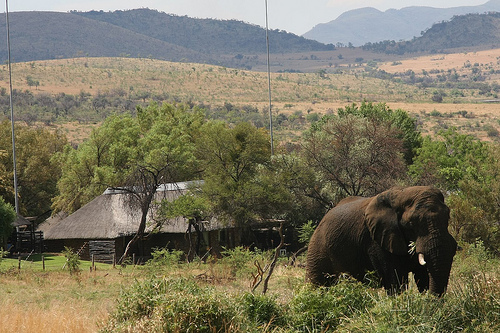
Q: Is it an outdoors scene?
A: Yes, it is outdoors.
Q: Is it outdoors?
A: Yes, it is outdoors.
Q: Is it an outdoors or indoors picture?
A: It is outdoors.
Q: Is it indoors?
A: No, it is outdoors.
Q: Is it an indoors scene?
A: No, it is outdoors.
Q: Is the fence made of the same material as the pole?
A: No, the fence is made of wood and the pole is made of metal.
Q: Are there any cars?
A: No, there are no cars.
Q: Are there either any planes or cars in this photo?
A: No, there are no cars or planes.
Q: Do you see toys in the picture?
A: No, there are no toys.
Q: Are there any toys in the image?
A: No, there are no toys.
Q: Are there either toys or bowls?
A: No, there are no toys or bowls.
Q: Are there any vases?
A: No, there are no vases.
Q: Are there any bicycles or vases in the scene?
A: No, there are no vases or bicycles.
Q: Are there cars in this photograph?
A: No, there are no cars.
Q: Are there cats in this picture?
A: No, there are no cats.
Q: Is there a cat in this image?
A: No, there are no cats.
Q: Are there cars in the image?
A: No, there are no cars.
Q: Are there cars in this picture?
A: No, there are no cars.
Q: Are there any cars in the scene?
A: No, there are no cars.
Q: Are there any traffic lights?
A: No, there are no traffic lights.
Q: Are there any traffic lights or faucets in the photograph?
A: No, there are no traffic lights or faucets.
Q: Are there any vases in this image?
A: No, there are no vases.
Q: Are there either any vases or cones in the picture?
A: No, there are no vases or cones.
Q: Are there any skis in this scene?
A: No, there are no skis.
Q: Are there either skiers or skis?
A: No, there are no skis or skiers.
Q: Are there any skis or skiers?
A: No, there are no skis or skiers.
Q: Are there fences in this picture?
A: Yes, there is a fence.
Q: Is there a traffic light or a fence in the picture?
A: Yes, there is a fence.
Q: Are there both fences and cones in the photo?
A: No, there is a fence but no cones.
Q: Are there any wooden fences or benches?
A: Yes, there is a wood fence.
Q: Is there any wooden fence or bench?
A: Yes, there is a wood fence.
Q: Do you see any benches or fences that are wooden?
A: Yes, the fence is wooden.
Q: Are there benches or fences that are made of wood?
A: Yes, the fence is made of wood.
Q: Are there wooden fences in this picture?
A: Yes, there is a wood fence.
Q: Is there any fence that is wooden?
A: Yes, there is a fence that is wooden.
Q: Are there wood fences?
A: Yes, there is a fence that is made of wood.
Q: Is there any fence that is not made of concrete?
A: Yes, there is a fence that is made of wood.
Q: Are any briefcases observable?
A: No, there are no briefcases.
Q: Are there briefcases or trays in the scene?
A: No, there are no briefcases or trays.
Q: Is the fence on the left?
A: Yes, the fence is on the left of the image.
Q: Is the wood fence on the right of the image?
A: No, the fence is on the left of the image.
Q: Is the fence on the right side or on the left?
A: The fence is on the left of the image.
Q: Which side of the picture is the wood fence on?
A: The fence is on the left of the image.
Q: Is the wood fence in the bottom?
A: Yes, the fence is in the bottom of the image.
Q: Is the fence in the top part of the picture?
A: No, the fence is in the bottom of the image.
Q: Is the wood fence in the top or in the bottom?
A: The fence is in the bottom of the image.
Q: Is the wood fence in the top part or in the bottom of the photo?
A: The fence is in the bottom of the image.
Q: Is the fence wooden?
A: Yes, the fence is wooden.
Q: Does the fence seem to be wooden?
A: Yes, the fence is wooden.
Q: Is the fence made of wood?
A: Yes, the fence is made of wood.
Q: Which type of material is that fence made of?
A: The fence is made of wood.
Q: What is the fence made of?
A: The fence is made of wood.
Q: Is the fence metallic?
A: No, the fence is wooden.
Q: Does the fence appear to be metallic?
A: No, the fence is wooden.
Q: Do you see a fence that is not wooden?
A: No, there is a fence but it is wooden.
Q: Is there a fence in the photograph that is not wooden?
A: No, there is a fence but it is wooden.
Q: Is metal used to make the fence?
A: No, the fence is made of wood.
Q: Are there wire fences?
A: No, there is a fence but it is made of wood.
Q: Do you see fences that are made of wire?
A: No, there is a fence but it is made of wood.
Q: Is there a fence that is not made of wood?
A: No, there is a fence but it is made of wood.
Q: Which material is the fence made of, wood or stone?
A: The fence is made of wood.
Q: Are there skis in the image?
A: No, there are no skis.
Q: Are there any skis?
A: No, there are no skis.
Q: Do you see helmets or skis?
A: No, there are no skis or helmets.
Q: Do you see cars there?
A: No, there are no cars.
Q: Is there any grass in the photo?
A: Yes, there is grass.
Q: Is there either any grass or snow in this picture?
A: Yes, there is grass.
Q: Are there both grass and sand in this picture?
A: No, there is grass but no sand.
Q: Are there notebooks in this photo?
A: No, there are no notebooks.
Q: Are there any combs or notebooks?
A: No, there are no notebooks or combs.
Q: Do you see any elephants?
A: Yes, there is an elephant.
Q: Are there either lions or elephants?
A: Yes, there is an elephant.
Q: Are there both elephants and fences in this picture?
A: Yes, there are both an elephant and a fence.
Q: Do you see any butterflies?
A: No, there are no butterflies.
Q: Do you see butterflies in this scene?
A: No, there are no butterflies.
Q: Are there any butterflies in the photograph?
A: No, there are no butterflies.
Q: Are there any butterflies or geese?
A: No, there are no butterflies or geese.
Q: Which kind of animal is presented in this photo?
A: The animal is an elephant.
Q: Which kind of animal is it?
A: The animal is an elephant.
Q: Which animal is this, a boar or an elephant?
A: That is an elephant.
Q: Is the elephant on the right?
A: Yes, the elephant is on the right of the image.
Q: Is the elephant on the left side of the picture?
A: No, the elephant is on the right of the image.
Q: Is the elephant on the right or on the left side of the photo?
A: The elephant is on the right of the image.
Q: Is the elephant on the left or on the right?
A: The elephant is on the right of the image.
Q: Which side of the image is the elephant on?
A: The elephant is on the right of the image.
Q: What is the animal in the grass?
A: The animal is an elephant.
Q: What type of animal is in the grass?
A: The animal is an elephant.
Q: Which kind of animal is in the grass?
A: The animal is an elephant.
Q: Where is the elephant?
A: The elephant is in the grass.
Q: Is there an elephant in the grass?
A: Yes, there is an elephant in the grass.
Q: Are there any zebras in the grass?
A: No, there is an elephant in the grass.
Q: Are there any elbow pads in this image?
A: No, there are no elbow pads.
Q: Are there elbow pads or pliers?
A: No, there are no elbow pads or pliers.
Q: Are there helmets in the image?
A: No, there are no helmets.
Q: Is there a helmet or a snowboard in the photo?
A: No, there are no helmets or snowboards.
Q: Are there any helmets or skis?
A: No, there are no skis or helmets.